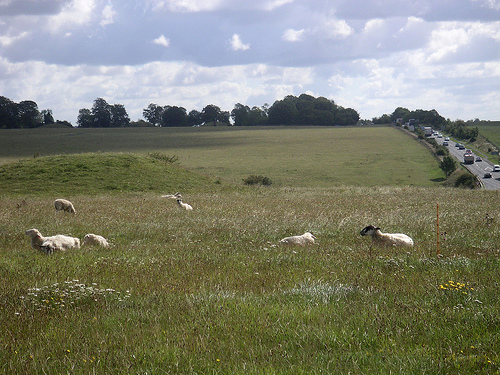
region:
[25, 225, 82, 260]
a white sheep laying in grass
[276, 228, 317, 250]
a white sheep laying in grass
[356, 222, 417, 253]
a white sheep laying in grass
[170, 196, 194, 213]
a white sheep laying in grass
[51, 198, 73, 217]
a white sheep laying in grass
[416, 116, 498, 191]
a two lane highway in distance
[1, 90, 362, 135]
a line of green trees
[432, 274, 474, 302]
a patch of yellow flowers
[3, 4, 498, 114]
a cloudy blue sky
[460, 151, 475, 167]
a truck on highway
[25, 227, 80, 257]
black and white sheep in field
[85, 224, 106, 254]
black and white sheep in field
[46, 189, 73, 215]
black and white sheep in field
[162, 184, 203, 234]
black and white sheep in field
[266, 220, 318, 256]
black and white sheep in field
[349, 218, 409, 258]
black and white sheep in field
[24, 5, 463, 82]
white and gray clouds in sky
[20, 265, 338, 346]
green grass and flowers in field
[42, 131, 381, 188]
green grass and flowers in field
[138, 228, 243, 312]
green grass and flowers in field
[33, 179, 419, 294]
Several sheep in a field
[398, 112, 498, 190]
Automobiles along a busy road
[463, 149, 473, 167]
White truck in the distance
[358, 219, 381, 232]
Sheep has black head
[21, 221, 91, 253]
Animal has wooly white body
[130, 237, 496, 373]
Green grass in foreground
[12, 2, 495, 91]
Sky is bright, yet cloudy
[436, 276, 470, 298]
Yellow flowers in the grass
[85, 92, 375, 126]
Line of trees past the field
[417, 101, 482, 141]
Trees alongside the road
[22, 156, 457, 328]
Sheeps are walking around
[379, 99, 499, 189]
A road in the background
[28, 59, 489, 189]
Trees in the distance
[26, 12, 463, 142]
Clouds are in the sky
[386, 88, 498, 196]
Cars are on the road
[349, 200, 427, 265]
This sheep has black fur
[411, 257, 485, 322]
Yellow flowers on the grass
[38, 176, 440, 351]
The grass has been cut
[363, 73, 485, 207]
Trees along the road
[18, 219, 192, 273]
These sheep are together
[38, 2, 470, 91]
The sky is cloudy.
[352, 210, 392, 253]
The sheep has a black face.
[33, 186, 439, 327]
The sheet are in the grass.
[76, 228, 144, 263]
The sheep is grazing.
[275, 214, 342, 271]
The sheep is laying down.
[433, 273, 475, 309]
The yellow flowers are in the grass.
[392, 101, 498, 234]
The road is close.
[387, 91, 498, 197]
The cars are driving on the road.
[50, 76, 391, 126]
The trees are leafy.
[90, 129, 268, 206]
The grass is tall.